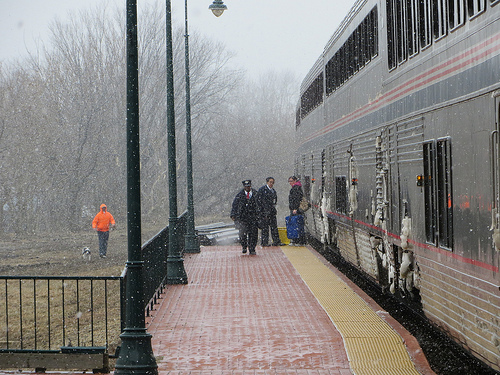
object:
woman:
[287, 175, 307, 245]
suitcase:
[285, 215, 302, 239]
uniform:
[230, 188, 261, 223]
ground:
[164, 257, 211, 303]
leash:
[89, 229, 95, 246]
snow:
[246, 108, 282, 147]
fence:
[0, 276, 122, 357]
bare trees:
[39, 21, 116, 190]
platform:
[141, 243, 431, 372]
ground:
[228, 264, 331, 308]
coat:
[92, 203, 117, 232]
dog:
[81, 244, 91, 262]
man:
[91, 202, 116, 259]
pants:
[98, 230, 110, 255]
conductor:
[230, 180, 268, 254]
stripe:
[280, 242, 415, 373]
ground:
[143, 336, 429, 374]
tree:
[141, 29, 172, 260]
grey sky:
[255, 17, 313, 46]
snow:
[7, 8, 106, 369]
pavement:
[142, 237, 431, 373]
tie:
[247, 192, 250, 200]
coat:
[230, 188, 264, 227]